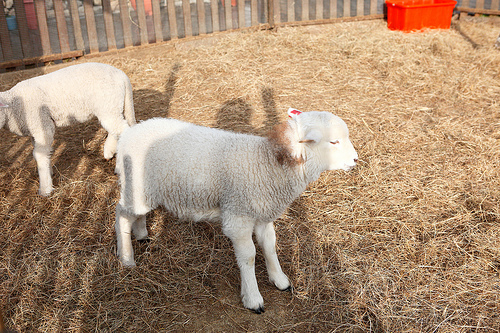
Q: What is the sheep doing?
A: Standing in pen.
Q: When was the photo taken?
A: In the afternoon.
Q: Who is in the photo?
A: No people.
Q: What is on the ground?
A: Hay.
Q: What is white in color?
A: The animals.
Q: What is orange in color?
A: A bucket.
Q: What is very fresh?
A: The hay.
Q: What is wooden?
A: The pen.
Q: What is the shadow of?
A: A person.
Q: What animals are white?
A: Lambs.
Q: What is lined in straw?
A: The pen.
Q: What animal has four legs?
A: The lamb.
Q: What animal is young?
A: The sheep.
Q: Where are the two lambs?
A: Straw.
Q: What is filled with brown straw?
A: Enclosure.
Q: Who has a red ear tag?
A: A lamb.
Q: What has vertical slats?
A: Fence.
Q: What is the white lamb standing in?
A: Straw.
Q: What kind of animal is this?
A: Lamb.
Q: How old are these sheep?
A: Young.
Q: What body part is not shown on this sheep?
A: The head.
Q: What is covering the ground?
A: Hay.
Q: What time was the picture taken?
A: In the day.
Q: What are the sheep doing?
A: Standing up.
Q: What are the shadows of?
A: The sheep.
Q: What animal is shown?
A: A baby.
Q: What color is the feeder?
A: Red.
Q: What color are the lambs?
A: White.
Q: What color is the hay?
A: Golden yellow.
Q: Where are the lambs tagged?
A: On their ears.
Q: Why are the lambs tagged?
A: To identify the owner.